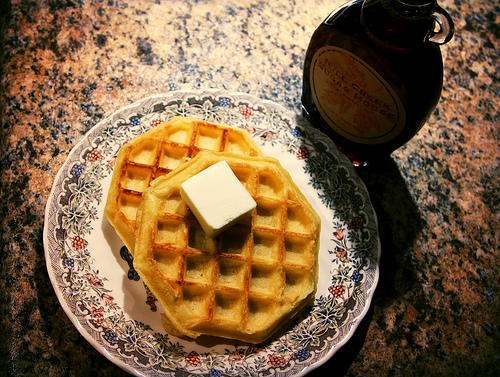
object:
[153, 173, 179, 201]
butter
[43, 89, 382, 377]
plate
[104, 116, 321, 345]
waffle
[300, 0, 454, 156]
bottle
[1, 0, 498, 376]
surface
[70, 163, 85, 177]
berry design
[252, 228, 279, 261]
square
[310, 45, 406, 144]
sticker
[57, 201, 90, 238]
leaf design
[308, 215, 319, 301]
edge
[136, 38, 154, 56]
spot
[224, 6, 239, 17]
spot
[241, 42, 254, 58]
spot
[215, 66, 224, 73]
spot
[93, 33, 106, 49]
spot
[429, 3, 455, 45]
glass handle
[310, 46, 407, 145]
orange leaf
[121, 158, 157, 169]
burned bit